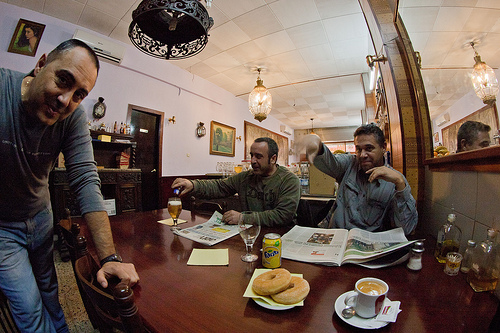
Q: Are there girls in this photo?
A: No, there are no girls.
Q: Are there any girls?
A: No, there are no girls.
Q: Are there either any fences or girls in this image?
A: No, there are no girls or fences.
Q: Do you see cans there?
A: Yes, there is a can.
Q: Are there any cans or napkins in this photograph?
A: Yes, there is a can.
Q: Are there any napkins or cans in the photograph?
A: Yes, there is a can.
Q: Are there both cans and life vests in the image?
A: No, there is a can but no life jackets.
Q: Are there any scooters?
A: No, there are no scooters.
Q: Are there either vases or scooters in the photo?
A: No, there are no scooters or vases.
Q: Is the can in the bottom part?
A: Yes, the can is in the bottom of the image.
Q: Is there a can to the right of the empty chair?
A: Yes, there is a can to the right of the chair.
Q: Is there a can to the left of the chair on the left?
A: No, the can is to the right of the chair.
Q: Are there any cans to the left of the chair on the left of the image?
A: No, the can is to the right of the chair.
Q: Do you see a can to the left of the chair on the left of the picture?
A: No, the can is to the right of the chair.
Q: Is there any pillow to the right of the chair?
A: No, there is a can to the right of the chair.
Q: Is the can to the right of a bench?
A: No, the can is to the right of a chair.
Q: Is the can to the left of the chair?
A: No, the can is to the right of the chair.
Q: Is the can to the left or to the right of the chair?
A: The can is to the right of the chair.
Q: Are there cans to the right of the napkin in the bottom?
A: Yes, there is a can to the right of the napkin.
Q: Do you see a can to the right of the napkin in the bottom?
A: Yes, there is a can to the right of the napkin.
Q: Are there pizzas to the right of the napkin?
A: No, there is a can to the right of the napkin.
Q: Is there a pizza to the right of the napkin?
A: No, there is a can to the right of the napkin.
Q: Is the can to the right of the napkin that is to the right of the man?
A: Yes, the can is to the right of the napkin.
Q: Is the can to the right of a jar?
A: No, the can is to the right of the napkin.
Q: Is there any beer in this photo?
A: Yes, there is beer.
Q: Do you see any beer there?
A: Yes, there is beer.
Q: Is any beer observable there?
A: Yes, there is beer.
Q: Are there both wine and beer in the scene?
A: No, there is beer but no wine.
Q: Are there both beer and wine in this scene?
A: No, there is beer but no wine.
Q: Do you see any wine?
A: No, there is no wine.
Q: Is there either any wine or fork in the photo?
A: No, there are no wine or forks.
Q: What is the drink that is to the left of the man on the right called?
A: The drink is beer.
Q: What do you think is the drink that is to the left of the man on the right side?
A: The drink is beer.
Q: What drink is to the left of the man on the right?
A: The drink is beer.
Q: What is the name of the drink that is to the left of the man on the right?
A: The drink is beer.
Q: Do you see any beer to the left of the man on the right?
A: Yes, there is beer to the left of the man.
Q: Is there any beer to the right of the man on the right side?
A: No, the beer is to the left of the man.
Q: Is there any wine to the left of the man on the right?
A: No, there is beer to the left of the man.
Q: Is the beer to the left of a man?
A: Yes, the beer is to the left of a man.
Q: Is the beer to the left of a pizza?
A: No, the beer is to the left of a man.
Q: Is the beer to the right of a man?
A: No, the beer is to the left of a man.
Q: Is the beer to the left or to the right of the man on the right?
A: The beer is to the left of the man.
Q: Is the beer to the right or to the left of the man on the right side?
A: The beer is to the left of the man.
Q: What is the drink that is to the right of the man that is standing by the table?
A: The drink is beer.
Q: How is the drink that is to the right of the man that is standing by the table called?
A: The drink is beer.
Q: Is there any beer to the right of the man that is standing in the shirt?
A: Yes, there is beer to the right of the man.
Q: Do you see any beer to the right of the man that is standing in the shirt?
A: Yes, there is beer to the right of the man.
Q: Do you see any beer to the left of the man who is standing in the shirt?
A: No, the beer is to the right of the man.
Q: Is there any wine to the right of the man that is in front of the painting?
A: No, there is beer to the right of the man.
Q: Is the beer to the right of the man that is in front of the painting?
A: Yes, the beer is to the right of the man.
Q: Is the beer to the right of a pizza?
A: No, the beer is to the right of the man.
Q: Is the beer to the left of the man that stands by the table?
A: No, the beer is to the right of the man.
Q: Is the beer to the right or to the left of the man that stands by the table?
A: The beer is to the right of the man.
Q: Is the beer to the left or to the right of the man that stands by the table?
A: The beer is to the right of the man.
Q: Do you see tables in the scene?
A: Yes, there is a table.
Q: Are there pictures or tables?
A: Yes, there is a table.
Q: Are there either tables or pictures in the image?
A: Yes, there is a table.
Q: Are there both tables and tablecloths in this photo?
A: No, there is a table but no tablecloths.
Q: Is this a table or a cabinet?
A: This is a table.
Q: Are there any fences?
A: No, there are no fences.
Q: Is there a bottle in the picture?
A: Yes, there is a bottle.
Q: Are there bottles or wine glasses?
A: Yes, there is a bottle.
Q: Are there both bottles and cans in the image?
A: Yes, there are both a bottle and a can.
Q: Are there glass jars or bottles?
A: Yes, there is a glass bottle.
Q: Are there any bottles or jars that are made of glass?
A: Yes, the bottle is made of glass.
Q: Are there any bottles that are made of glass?
A: Yes, there is a bottle that is made of glass.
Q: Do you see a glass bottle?
A: Yes, there is a bottle that is made of glass.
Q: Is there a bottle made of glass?
A: Yes, there is a bottle that is made of glass.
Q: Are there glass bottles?
A: Yes, there is a bottle that is made of glass.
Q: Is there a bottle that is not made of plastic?
A: Yes, there is a bottle that is made of glass.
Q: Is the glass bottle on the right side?
A: Yes, the bottle is on the right of the image.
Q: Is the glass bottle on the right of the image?
A: Yes, the bottle is on the right of the image.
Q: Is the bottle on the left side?
A: No, the bottle is on the right of the image.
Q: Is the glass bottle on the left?
A: No, the bottle is on the right of the image.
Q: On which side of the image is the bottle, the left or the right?
A: The bottle is on the right of the image.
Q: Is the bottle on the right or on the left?
A: The bottle is on the right of the image.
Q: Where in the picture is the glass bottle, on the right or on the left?
A: The bottle is on the right of the image.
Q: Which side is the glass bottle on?
A: The bottle is on the right of the image.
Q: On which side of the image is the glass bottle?
A: The bottle is on the right of the image.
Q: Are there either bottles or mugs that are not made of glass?
A: No, there is a bottle but it is made of glass.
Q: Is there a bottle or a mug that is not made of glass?
A: No, there is a bottle but it is made of glass.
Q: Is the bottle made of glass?
A: Yes, the bottle is made of glass.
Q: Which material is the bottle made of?
A: The bottle is made of glass.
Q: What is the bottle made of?
A: The bottle is made of glass.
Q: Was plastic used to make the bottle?
A: No, the bottle is made of glass.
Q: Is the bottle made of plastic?
A: No, the bottle is made of glass.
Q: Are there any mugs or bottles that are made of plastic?
A: No, there is a bottle but it is made of glass.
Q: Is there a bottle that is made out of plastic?
A: No, there is a bottle but it is made of glass.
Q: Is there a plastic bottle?
A: No, there is a bottle but it is made of glass.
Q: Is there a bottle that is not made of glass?
A: No, there is a bottle but it is made of glass.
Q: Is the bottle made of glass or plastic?
A: The bottle is made of glass.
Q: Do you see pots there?
A: No, there are no pots.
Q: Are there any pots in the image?
A: No, there are no pots.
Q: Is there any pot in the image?
A: No, there are no pots.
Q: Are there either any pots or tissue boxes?
A: No, there are no pots or tissue boxes.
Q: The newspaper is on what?
A: The newspaper is on the table.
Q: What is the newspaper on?
A: The newspaper is on the table.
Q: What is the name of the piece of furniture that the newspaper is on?
A: The piece of furniture is a table.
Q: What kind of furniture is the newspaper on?
A: The newspaper is on the table.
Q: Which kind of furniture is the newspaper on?
A: The newspaper is on the table.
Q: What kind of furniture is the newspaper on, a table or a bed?
A: The newspaper is on a table.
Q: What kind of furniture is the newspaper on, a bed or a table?
A: The newspaper is on a table.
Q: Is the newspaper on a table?
A: Yes, the newspaper is on a table.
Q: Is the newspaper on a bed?
A: No, the newspaper is on a table.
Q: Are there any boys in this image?
A: No, there are no boys.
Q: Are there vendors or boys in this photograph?
A: No, there are no boys or vendors.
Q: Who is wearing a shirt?
A: The man is wearing a shirt.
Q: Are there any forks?
A: No, there are no forks.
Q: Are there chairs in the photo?
A: Yes, there is a chair.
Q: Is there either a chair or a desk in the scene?
A: Yes, there is a chair.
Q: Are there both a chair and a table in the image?
A: Yes, there are both a chair and a table.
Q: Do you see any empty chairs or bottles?
A: Yes, there is an empty chair.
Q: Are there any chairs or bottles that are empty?
A: Yes, the chair is empty.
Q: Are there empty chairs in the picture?
A: Yes, there is an empty chair.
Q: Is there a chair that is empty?
A: Yes, there is a chair that is empty.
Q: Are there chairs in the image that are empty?
A: Yes, there is a chair that is empty.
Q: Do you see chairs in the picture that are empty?
A: Yes, there is a chair that is empty.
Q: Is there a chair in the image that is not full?
A: Yes, there is a empty chair.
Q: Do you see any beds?
A: No, there are no beds.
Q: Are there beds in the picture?
A: No, there are no beds.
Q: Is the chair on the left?
A: Yes, the chair is on the left of the image.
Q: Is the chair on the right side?
A: No, the chair is on the left of the image.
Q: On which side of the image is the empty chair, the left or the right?
A: The chair is on the left of the image.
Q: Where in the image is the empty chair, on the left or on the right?
A: The chair is on the left of the image.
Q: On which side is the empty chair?
A: The chair is on the left of the image.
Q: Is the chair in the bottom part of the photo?
A: Yes, the chair is in the bottom of the image.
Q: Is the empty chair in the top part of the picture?
A: No, the chair is in the bottom of the image.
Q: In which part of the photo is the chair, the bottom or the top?
A: The chair is in the bottom of the image.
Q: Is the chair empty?
A: Yes, the chair is empty.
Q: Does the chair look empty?
A: Yes, the chair is empty.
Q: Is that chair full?
A: No, the chair is empty.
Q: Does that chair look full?
A: No, the chair is empty.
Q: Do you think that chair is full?
A: No, the chair is empty.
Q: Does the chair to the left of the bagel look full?
A: No, the chair is empty.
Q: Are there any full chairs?
A: No, there is a chair but it is empty.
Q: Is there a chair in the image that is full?
A: No, there is a chair but it is empty.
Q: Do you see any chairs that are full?
A: No, there is a chair but it is empty.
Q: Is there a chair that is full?
A: No, there is a chair but it is empty.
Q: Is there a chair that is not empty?
A: No, there is a chair but it is empty.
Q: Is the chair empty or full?
A: The chair is empty.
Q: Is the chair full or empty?
A: The chair is empty.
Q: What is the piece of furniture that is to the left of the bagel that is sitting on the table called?
A: The piece of furniture is a chair.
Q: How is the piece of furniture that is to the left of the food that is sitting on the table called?
A: The piece of furniture is a chair.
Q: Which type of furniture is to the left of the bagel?
A: The piece of furniture is a chair.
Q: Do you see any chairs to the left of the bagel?
A: Yes, there is a chair to the left of the bagel.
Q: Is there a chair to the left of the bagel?
A: Yes, there is a chair to the left of the bagel.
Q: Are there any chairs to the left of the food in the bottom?
A: Yes, there is a chair to the left of the bagel.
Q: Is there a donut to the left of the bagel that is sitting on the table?
A: No, there is a chair to the left of the bagel.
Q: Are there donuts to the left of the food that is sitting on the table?
A: No, there is a chair to the left of the bagel.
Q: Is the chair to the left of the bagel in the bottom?
A: Yes, the chair is to the left of the bagel.